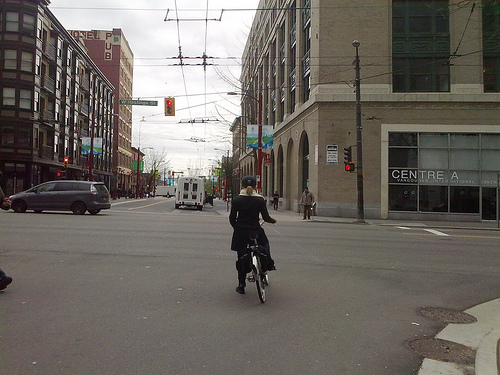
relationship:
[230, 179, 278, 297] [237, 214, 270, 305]
woman on bike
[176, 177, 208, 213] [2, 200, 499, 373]
bus on street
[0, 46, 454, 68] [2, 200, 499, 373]
wire above street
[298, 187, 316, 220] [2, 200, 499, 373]
man by street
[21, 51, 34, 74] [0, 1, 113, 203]
window on building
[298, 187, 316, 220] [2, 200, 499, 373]
man on street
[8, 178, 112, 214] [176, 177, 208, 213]
car by bus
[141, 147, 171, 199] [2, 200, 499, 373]
tree by street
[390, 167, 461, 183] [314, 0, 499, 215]
lettering on wall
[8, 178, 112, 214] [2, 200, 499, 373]
car on street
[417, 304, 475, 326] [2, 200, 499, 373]
cover on street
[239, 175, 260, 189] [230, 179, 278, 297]
helmet on woman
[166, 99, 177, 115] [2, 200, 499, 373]
light over street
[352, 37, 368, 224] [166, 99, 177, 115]
pole with light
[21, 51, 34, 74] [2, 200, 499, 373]
window by street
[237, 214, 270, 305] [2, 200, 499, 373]
bike on street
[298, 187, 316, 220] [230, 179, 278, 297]
man behind woman